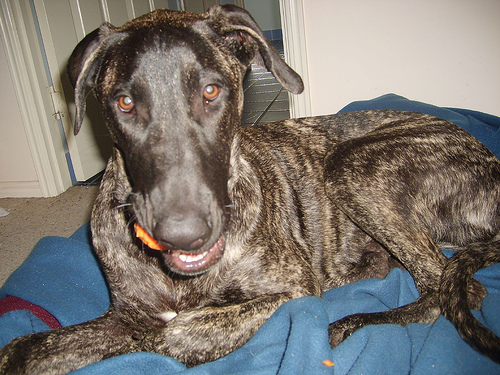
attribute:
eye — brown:
[200, 84, 217, 101]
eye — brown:
[115, 94, 134, 111]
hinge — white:
[47, 82, 68, 124]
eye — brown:
[111, 91, 137, 114]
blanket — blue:
[0, 92, 500, 373]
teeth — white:
[174, 229, 212, 274]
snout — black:
[118, 123, 228, 250]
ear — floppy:
[64, 22, 115, 134]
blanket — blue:
[244, 288, 405, 367]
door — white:
[31, 0, 292, 184]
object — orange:
[131, 225, 166, 252]